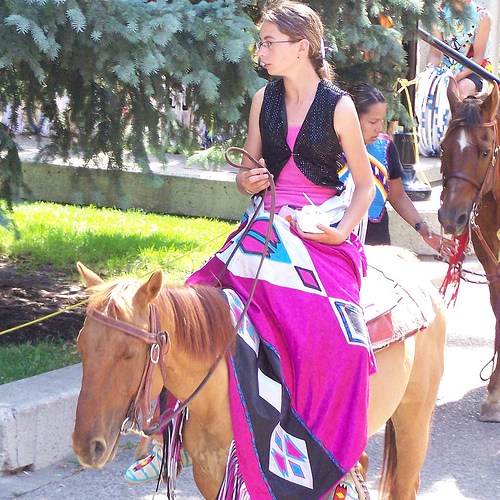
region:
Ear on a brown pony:
[57, 256, 114, 296]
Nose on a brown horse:
[55, 360, 145, 498]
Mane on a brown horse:
[87, 269, 266, 356]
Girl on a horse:
[221, 7, 401, 282]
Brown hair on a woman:
[248, 3, 340, 95]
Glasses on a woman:
[246, 10, 330, 84]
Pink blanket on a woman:
[198, 192, 390, 454]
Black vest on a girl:
[242, 71, 404, 204]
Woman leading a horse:
[333, 74, 420, 246]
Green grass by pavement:
[18, 196, 194, 281]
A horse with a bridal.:
[70, 243, 447, 497]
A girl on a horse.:
[71, 2, 448, 498]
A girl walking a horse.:
[338, 82, 460, 261]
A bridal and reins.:
[88, 145, 274, 440]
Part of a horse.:
[436, 75, 498, 423]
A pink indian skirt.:
[183, 194, 378, 497]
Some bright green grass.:
[1, 195, 241, 386]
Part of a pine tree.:
[1, 73, 415, 243]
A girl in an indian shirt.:
[337, 82, 461, 259]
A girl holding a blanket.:
[413, 1, 492, 157]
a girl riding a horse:
[126, 2, 368, 499]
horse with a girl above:
[51, 238, 452, 498]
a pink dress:
[140, 120, 371, 477]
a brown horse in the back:
[424, 73, 499, 416]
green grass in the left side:
[1, 187, 301, 376]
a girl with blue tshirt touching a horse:
[346, 83, 446, 248]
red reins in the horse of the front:
[84, 137, 279, 434]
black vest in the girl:
[249, 66, 363, 193]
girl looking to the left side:
[121, 1, 377, 491]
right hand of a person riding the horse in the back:
[452, 8, 499, 94]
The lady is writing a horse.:
[206, 23, 377, 313]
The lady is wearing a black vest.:
[256, 88, 346, 195]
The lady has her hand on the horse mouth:
[357, 101, 482, 263]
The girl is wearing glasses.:
[248, 30, 311, 47]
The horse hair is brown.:
[163, 278, 259, 365]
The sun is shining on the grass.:
[73, 208, 241, 274]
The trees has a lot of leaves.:
[49, 19, 245, 137]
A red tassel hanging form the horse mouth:
[433, 226, 471, 297]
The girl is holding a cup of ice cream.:
[287, 201, 353, 248]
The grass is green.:
[63, 144, 220, 272]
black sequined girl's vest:
[255, 81, 350, 188]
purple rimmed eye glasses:
[251, 34, 301, 49]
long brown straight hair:
[264, 6, 336, 75]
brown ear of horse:
[76, 260, 106, 290]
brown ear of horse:
[135, 273, 168, 305]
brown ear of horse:
[445, 74, 460, 113]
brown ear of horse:
[481, 82, 498, 111]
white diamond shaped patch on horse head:
[455, 126, 470, 155]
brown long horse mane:
[87, 268, 237, 355]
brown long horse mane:
[452, 92, 487, 128]